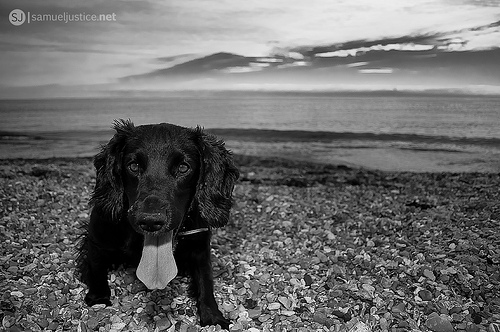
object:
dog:
[80, 118, 240, 327]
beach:
[3, 154, 499, 332]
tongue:
[135, 230, 177, 290]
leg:
[185, 240, 231, 330]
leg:
[82, 241, 111, 308]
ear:
[194, 129, 240, 225]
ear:
[91, 124, 132, 224]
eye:
[178, 162, 190, 173]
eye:
[130, 162, 139, 172]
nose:
[137, 220, 164, 232]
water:
[1, 93, 500, 142]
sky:
[0, 0, 500, 90]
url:
[9, 9, 116, 26]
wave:
[10, 125, 498, 148]